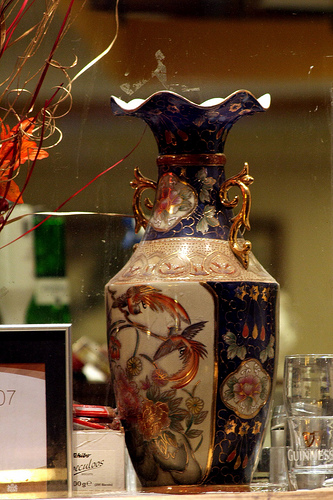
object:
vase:
[103, 83, 278, 486]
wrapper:
[72, 416, 109, 430]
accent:
[130, 166, 156, 234]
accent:
[219, 160, 253, 270]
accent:
[155, 153, 226, 165]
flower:
[0, 111, 47, 225]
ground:
[252, 110, 270, 129]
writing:
[71, 452, 113, 486]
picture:
[0, 323, 71, 496]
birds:
[111, 280, 208, 389]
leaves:
[196, 204, 220, 236]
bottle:
[282, 353, 331, 486]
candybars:
[72, 402, 122, 431]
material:
[0, 3, 121, 232]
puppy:
[102, 85, 280, 409]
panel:
[197, 274, 278, 483]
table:
[0, 470, 331, 499]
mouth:
[107, 89, 271, 118]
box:
[72, 427, 125, 493]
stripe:
[206, 363, 218, 469]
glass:
[269, 400, 325, 489]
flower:
[108, 288, 214, 483]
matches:
[71, 404, 118, 428]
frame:
[0, 323, 72, 499]